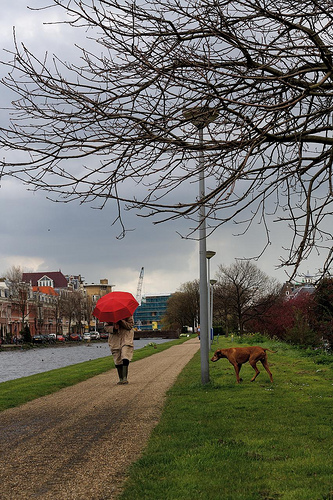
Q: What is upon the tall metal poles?
A: Street lights.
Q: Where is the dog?
A: On the grass.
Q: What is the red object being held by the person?
A: Umbrella.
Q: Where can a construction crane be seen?
A: Background.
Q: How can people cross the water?
A: Bridge.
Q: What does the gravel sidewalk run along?
A: Water.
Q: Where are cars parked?
A: Street in background.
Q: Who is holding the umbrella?
A: The person.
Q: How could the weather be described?
A: Rainy.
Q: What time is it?
A: Afternoon.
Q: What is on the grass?
A: A dog.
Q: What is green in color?
A: The grass.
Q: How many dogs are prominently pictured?
A: One.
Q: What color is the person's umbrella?
A: Red.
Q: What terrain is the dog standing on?
A: Grass.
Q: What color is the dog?
A: Brown.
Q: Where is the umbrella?
A: In the person's hands.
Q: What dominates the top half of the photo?
A: Tree.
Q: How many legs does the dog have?
A: Four.